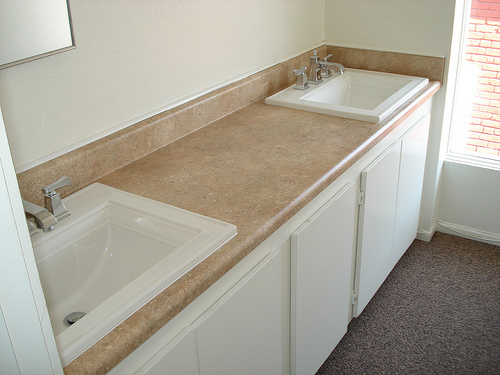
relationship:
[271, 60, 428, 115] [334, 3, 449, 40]
sink near wall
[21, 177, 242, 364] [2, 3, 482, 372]
sinks in bathroom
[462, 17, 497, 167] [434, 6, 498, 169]
wall outside window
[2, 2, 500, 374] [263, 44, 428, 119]
bathroom has sinks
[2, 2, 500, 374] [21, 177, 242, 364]
bathroom has sinks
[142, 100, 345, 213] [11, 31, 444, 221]
counter has backsplash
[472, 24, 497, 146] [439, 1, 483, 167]
brick wall seen through window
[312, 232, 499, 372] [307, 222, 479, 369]
carpet on floor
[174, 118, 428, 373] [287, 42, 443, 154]
cabinets under sink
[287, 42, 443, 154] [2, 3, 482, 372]
sink in bathroom